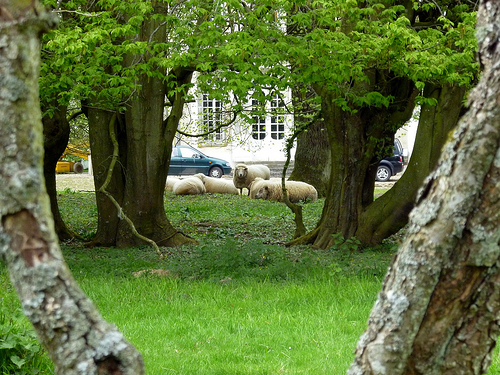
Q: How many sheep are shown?
A: 4.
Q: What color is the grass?
A: Green.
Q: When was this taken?
A: Daytime.